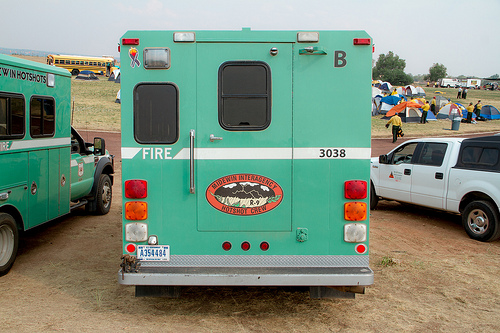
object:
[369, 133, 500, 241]
car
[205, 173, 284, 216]
logo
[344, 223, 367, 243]
light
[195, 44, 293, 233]
door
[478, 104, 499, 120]
tent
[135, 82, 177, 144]
window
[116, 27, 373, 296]
ambulance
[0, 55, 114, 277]
ambulance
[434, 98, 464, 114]
desk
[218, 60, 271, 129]
door window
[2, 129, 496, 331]
dirt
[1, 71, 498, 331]
ground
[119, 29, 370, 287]
back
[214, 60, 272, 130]
window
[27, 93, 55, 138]
window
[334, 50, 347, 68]
b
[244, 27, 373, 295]
part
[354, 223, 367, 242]
part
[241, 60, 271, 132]
part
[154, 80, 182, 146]
part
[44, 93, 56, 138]
part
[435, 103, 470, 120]
tent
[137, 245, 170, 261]
license plate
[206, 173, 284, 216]
design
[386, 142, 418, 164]
window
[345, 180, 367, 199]
light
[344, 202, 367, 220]
light